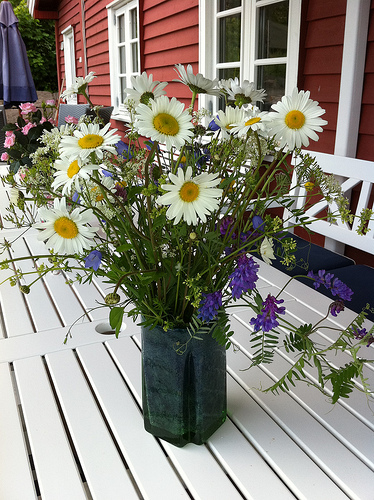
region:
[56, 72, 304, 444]
daisies in a vace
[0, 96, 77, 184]
pink flowers on the table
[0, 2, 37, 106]
a faded blue patio umbrella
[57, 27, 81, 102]
the white back door into the house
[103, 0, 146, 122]
a white framed window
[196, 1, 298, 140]
a white framed window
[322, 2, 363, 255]
a white downspout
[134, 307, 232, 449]
a green vase on the table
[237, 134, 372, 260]
a white bench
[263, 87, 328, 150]
White petal flowers with yellow centers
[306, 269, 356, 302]
Dark purple flowers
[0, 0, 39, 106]
Closed purple patio umbrella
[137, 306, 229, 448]
Green tinted glass vase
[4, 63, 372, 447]
Flowers in a green vase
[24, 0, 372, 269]
Red painted house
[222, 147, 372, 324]
White wood bench with blue cushions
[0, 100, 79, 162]
Light pink roses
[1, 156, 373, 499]
Flowers on a white wood table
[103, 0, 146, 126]
White wood framed windows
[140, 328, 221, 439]
a vase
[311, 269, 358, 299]
the flower is blue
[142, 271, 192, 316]
the stem of the flowers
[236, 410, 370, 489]
the table is white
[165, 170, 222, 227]
a flower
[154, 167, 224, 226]
the flower is white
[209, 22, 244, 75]
a window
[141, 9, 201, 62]
the house is red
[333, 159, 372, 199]
the chair is white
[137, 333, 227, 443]
the vase is on the table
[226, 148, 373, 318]
White bench in front of table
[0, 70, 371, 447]
Flower vase on top of white table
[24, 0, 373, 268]
Red house behind white bench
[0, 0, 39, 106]
Large purple umbrella in front of window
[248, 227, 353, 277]
Blue cushion on white bench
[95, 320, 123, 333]
Hole on white table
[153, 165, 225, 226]
Small white flower in vase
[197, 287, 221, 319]
Small purple flower in vase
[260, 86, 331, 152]
Small white flower in vase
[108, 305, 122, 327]
Green leaf in vase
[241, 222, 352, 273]
a blue cushion on a bench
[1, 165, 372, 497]
a long white table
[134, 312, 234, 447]
a green vase on a table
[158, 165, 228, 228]
a daisy in a vase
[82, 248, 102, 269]
a small blue flower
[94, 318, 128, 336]
a hold in the center of a table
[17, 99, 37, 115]
a pink rose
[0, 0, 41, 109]
a blue folded down umbrella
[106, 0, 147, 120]
a window in a house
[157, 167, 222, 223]
flower next to flower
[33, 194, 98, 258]
flower next to flower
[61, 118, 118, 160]
flower next to flower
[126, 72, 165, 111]
flower behind flower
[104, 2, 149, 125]
window has white trim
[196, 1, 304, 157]
window has white trim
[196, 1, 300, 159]
window on side of building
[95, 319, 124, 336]
hole in top of table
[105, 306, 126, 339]
a leaf on a stem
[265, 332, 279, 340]
a leaf on a stem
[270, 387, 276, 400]
a leaf on a stem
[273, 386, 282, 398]
a leaf on a stem